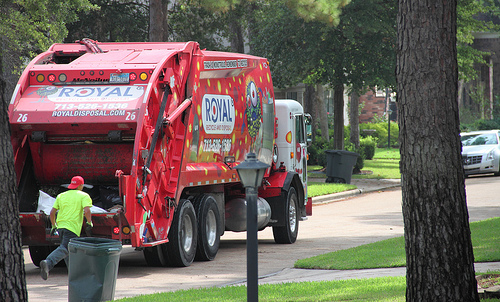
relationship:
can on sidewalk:
[66, 237, 121, 302] [113, 270, 224, 297]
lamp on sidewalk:
[234, 153, 269, 187] [234, 243, 494, 288]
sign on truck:
[193, 89, 243, 141] [6, 57, 321, 268]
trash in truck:
[67, 231, 127, 300] [6, 35, 314, 265]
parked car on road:
[461, 124, 495, 180] [10, 161, 499, 302]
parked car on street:
[460, 129, 500, 178] [2, 131, 499, 301]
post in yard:
[215, 147, 283, 295] [112, 265, 491, 302]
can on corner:
[64, 236, 128, 300] [313, 179, 419, 209]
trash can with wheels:
[314, 144, 367, 196] [325, 170, 351, 180]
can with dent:
[66, 237, 121, 302] [70, 263, 102, 299]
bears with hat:
[40, 175, 94, 280] [59, 174, 86, 189]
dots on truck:
[183, 54, 256, 180] [121, 51, 324, 234]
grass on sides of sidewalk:
[115, 274, 497, 299] [59, 179, 499, 300]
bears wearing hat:
[40, 175, 94, 280] [57, 160, 97, 192]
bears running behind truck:
[40, 175, 94, 280] [6, 35, 314, 265]